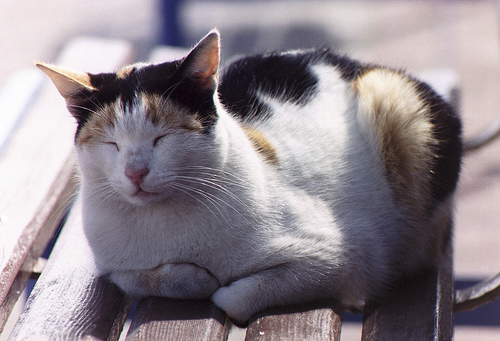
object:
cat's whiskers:
[152, 163, 264, 229]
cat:
[32, 27, 470, 322]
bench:
[0, 30, 461, 340]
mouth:
[121, 181, 160, 201]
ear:
[180, 28, 226, 85]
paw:
[149, 261, 220, 302]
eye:
[151, 130, 179, 147]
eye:
[97, 136, 122, 151]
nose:
[122, 153, 153, 183]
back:
[208, 45, 388, 182]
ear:
[30, 58, 96, 109]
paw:
[207, 280, 259, 328]